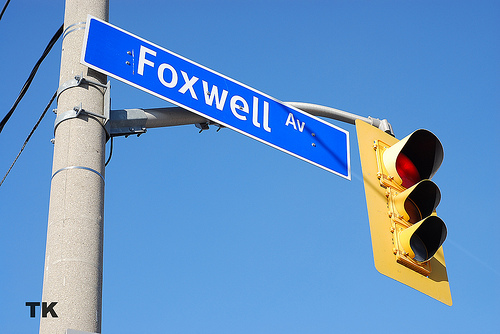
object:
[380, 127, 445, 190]
red light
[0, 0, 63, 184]
utility lines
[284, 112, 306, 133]
abbreviation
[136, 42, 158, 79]
letter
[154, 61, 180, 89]
letter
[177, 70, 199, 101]
letter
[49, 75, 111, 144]
brackets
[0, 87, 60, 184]
power cable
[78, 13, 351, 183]
foxwell av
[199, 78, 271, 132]
letter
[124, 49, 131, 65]
bolts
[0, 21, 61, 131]
cable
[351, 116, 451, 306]
stop light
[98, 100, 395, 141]
pole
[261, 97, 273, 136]
white letter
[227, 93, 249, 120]
white letter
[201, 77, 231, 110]
white letter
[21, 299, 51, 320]
identification mark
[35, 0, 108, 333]
pole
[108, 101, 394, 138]
arm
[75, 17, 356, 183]
street name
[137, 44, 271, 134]
foxwell